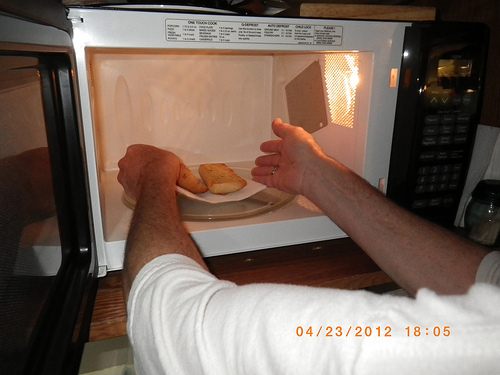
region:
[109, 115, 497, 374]
A person heating food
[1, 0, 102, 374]
An open microwave door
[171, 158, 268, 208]
Food on a napkin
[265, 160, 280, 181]
Ring around a finger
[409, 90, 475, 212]
Buttons on the microwave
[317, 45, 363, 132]
Light inside the microwave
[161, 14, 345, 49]
Warning labels on microwave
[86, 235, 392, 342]
A brown wooden countertop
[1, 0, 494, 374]
A black and white microwave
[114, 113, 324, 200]
A pair of two hands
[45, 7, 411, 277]
white interior of microwave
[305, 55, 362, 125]
light shining through dotted panel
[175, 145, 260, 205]
rectangular food on paper napkin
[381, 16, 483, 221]
black panel on side of oven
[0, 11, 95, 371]
black interior of microwave door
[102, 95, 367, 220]
hands reaching for food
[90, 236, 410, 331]
wood surface under microwave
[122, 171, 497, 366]
white sleeves over hairy arms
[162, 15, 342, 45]
black writing on white label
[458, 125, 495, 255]
glass jar to side of microwave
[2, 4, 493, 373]
microwave with open door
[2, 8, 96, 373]
black door with window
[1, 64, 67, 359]
reflection on window surface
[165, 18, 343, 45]
white label with black words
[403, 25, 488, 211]
buttons on black microwave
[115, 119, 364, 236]
two hands on white paper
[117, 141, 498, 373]
white sleeve on arm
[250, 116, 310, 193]
silver ring on finger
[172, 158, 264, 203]
food on white paper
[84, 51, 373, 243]
light on right wall of microwave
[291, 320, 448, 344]
date on the photo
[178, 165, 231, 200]
hot pocket on plate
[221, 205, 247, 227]
edge of glass plate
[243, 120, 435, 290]
arm of the person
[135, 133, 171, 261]
arm of the person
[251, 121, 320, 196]
hand of the person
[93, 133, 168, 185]
hand of the person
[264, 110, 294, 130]
finger on the hand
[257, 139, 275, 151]
finger on the hand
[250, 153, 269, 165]
finger on the hand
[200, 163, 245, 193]
hot pocket inside of microwave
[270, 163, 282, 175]
silver ring on mans right hand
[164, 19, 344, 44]
white instruction label on microwave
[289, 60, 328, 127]
sliver metal plate inside of microwave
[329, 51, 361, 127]
light on inside of black microwave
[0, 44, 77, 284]
glass door of black microwave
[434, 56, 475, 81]
clear plastic display screen on microwave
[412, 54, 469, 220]
control panel on black microwave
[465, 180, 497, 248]
glass cheese container with metal top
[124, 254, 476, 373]
man wear white shirt reaching inside of microwave